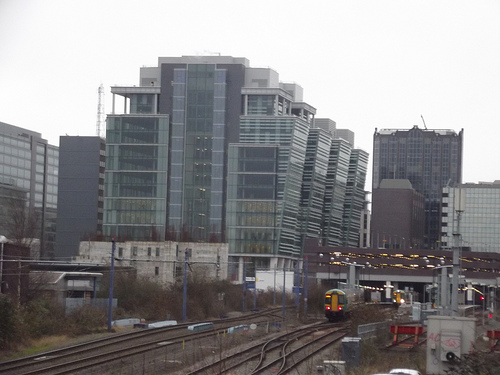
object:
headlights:
[337, 306, 342, 312]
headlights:
[325, 305, 329, 311]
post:
[104, 239, 117, 334]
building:
[255, 92, 351, 243]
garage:
[318, 244, 500, 273]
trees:
[2, 193, 46, 323]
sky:
[1, 2, 500, 54]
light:
[478, 294, 485, 300]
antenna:
[96, 86, 103, 139]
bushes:
[2, 301, 35, 346]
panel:
[425, 308, 480, 374]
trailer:
[113, 309, 143, 329]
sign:
[390, 323, 424, 336]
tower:
[132, 56, 286, 94]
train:
[323, 281, 348, 322]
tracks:
[248, 315, 311, 374]